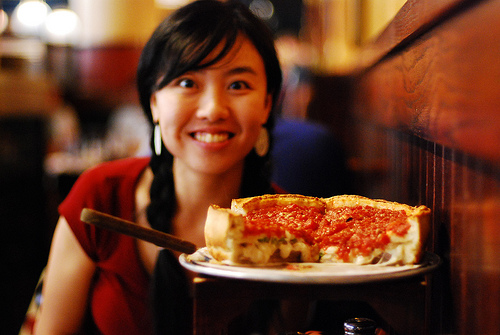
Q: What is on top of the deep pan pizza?
A: Tomato sauce?.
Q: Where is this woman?
A: In the restaurant.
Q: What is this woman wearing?
A: A red short sleeve blouse.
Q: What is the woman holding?
A: A deep pan pizza with tomato sauce on the top.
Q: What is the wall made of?
A: Wood.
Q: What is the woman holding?
A: Food.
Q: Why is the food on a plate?
A: For serving.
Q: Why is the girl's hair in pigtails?
A: Easy to manage.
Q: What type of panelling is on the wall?
A: Wood panelling.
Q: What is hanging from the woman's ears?
A: Earrings.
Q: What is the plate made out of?
A: Ceramic.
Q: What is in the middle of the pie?
A: Cheese.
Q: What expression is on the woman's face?
A: Happiness.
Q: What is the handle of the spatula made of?
A: Wood.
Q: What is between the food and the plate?
A: Spatula.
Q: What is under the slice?
A: Scooper.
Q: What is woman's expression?
A: Smiling.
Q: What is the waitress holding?
A: Stuffed pizza.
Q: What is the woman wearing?
A: Earrings.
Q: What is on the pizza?
A: Pepperoni.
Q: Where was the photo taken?
A: Chicago.